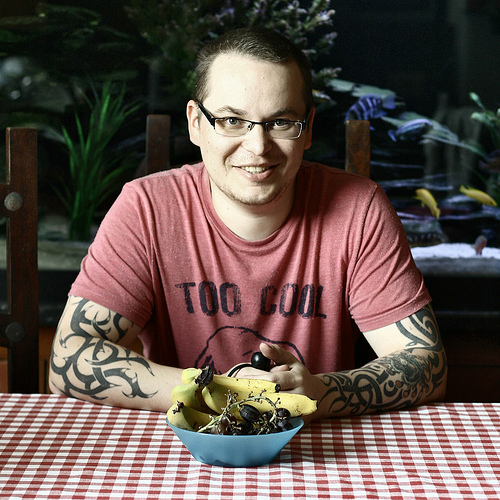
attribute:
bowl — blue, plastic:
[165, 417, 304, 468]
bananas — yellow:
[167, 365, 317, 429]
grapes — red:
[194, 387, 293, 436]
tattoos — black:
[319, 302, 447, 413]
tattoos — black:
[47, 293, 158, 399]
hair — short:
[188, 25, 315, 111]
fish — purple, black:
[344, 94, 388, 132]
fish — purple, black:
[388, 118, 435, 143]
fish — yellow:
[459, 183, 499, 210]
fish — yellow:
[414, 186, 441, 220]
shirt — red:
[68, 159, 434, 374]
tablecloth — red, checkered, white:
[1, 392, 500, 499]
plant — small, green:
[46, 70, 147, 241]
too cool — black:
[174, 280, 329, 320]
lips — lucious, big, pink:
[233, 161, 282, 182]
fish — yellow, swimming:
[415, 180, 497, 218]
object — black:
[226, 351, 276, 377]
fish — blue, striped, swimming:
[342, 93, 432, 143]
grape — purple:
[239, 402, 261, 421]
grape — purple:
[275, 407, 292, 424]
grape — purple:
[275, 417, 295, 433]